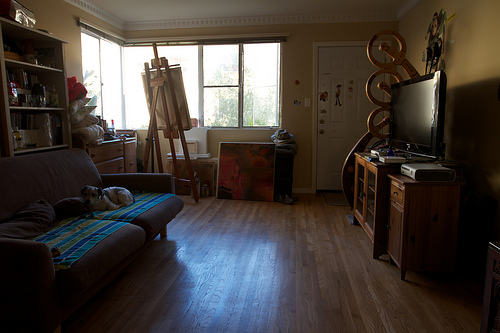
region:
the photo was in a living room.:
[14, 0, 490, 326]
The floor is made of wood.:
[97, 179, 469, 329]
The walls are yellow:
[1, 0, 491, 242]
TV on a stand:
[345, 62, 455, 166]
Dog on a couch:
[68, 176, 144, 210]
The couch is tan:
[5, 143, 189, 325]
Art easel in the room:
[125, 31, 217, 209]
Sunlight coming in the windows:
[63, 30, 296, 137]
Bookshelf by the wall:
[0, 18, 100, 192]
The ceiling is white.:
[53, 0, 428, 26]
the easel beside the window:
[137, 49, 214, 204]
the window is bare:
[186, 47, 296, 129]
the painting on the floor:
[208, 137, 310, 216]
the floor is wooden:
[3, 175, 493, 327]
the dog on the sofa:
[77, 170, 141, 223]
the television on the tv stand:
[373, 77, 468, 199]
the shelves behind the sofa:
[2, 50, 76, 140]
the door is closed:
[310, 42, 390, 207]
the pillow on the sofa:
[12, 194, 72, 246]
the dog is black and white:
[77, 170, 150, 225]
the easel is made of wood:
[130, 51, 215, 203]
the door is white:
[307, 31, 412, 198]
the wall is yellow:
[0, 0, 497, 177]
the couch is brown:
[0, 134, 197, 306]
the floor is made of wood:
[33, 169, 485, 330]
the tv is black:
[378, 54, 464, 185]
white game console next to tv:
[389, 149, 450, 197]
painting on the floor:
[202, 131, 286, 213]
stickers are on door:
[309, 56, 373, 129]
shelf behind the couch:
[0, 14, 82, 181]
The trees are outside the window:
[173, 28, 308, 159]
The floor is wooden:
[165, 229, 330, 326]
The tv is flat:
[372, 58, 487, 221]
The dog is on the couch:
[31, 152, 176, 273]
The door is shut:
[299, 31, 386, 197]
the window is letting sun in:
[134, 35, 231, 225]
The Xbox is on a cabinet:
[391, 153, 463, 227]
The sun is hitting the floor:
[166, 222, 271, 327]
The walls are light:
[286, 38, 328, 184]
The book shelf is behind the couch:
[4, 20, 94, 163]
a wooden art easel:
[137, 56, 201, 197]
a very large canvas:
[143, 65, 192, 134]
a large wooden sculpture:
[337, 34, 418, 204]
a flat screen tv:
[389, 68, 448, 164]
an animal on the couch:
[85, 180, 133, 211]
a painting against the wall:
[216, 139, 281, 205]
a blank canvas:
[182, 140, 200, 155]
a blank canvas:
[177, 122, 207, 154]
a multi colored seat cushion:
[35, 203, 143, 285]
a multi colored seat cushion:
[83, 171, 180, 234]